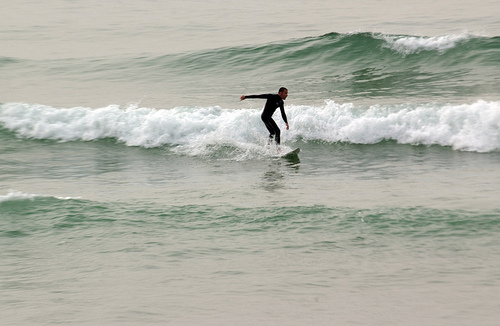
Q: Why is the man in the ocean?
A: Surfing.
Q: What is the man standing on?
A: Surfboard.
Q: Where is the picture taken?
A: Ocean.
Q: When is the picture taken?
A: During the daytime.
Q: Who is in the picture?
A: A man surfing.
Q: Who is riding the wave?
A: Surfer.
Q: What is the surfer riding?
A: Wave.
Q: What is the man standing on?
A: Surfboard.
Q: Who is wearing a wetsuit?
A: Surfer.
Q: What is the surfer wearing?
A: Wetsuit.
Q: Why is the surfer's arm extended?
A: Balance.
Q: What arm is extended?
A: Left.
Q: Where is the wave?
A: Behind the surfer.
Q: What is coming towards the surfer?
A: A big wave.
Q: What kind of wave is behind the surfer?
A: White foamy wave.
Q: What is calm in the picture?
A: Ocean water.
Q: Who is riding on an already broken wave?
A: Surfer.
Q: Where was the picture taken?
A: The ocean.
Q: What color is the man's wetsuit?
A: Black.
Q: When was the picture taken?
A: During the day.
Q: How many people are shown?
A: 1.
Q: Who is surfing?
A: A man.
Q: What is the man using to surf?
A: A surfboard.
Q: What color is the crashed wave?
A: White.